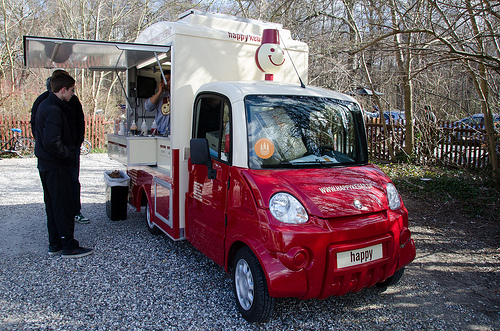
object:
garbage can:
[102, 168, 132, 222]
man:
[29, 72, 93, 261]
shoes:
[44, 242, 95, 259]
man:
[35, 71, 94, 259]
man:
[416, 98, 444, 143]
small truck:
[112, 17, 418, 292]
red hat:
[258, 29, 283, 45]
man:
[143, 77, 170, 133]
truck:
[20, 8, 418, 323]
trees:
[330, 2, 498, 92]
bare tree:
[328, 2, 462, 161]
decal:
[251, 135, 276, 160]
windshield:
[246, 94, 370, 169]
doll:
[257, 30, 286, 79]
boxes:
[220, 97, 310, 168]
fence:
[364, 114, 499, 171]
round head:
[252, 26, 284, 73]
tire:
[227, 243, 272, 325]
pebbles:
[4, 153, 468, 328]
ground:
[1, 151, 499, 331]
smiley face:
[253, 26, 286, 74]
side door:
[21, 33, 171, 85]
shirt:
[32, 94, 75, 168]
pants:
[37, 156, 80, 249]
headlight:
[267, 191, 311, 225]